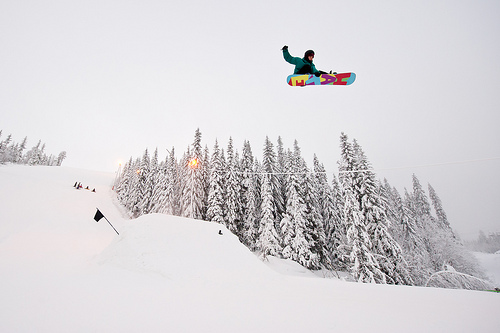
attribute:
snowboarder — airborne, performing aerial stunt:
[280, 43, 359, 88]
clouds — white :
[36, 30, 423, 158]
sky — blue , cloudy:
[16, 7, 496, 254]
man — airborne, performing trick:
[280, 45, 325, 73]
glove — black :
[280, 42, 292, 56]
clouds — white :
[306, 90, 488, 138]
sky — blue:
[0, 0, 277, 145]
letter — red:
[333, 74, 348, 85]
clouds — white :
[36, 17, 145, 106]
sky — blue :
[0, 0, 497, 240]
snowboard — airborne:
[275, 40, 363, 99]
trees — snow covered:
[110, 125, 488, 290]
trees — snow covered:
[2, 132, 65, 164]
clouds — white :
[2, 1, 499, 252]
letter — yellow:
[291, 73, 305, 87]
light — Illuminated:
[189, 157, 197, 217]